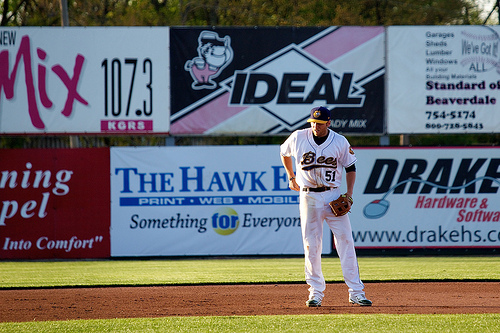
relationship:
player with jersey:
[278, 106, 375, 309] [276, 124, 361, 189]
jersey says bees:
[276, 124, 361, 189] [300, 150, 339, 165]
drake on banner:
[370, 157, 500, 194] [340, 156, 498, 248]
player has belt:
[278, 106, 375, 309] [303, 186, 336, 193]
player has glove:
[278, 106, 375, 309] [330, 193, 358, 218]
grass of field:
[4, 256, 500, 287] [5, 259, 499, 333]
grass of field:
[18, 315, 486, 332] [5, 259, 499, 333]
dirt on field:
[5, 285, 499, 312] [5, 259, 499, 333]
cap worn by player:
[303, 108, 336, 123] [278, 106, 375, 309]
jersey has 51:
[276, 124, 361, 189] [327, 167, 335, 184]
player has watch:
[278, 106, 375, 309] [289, 177, 295, 182]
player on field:
[278, 106, 375, 309] [5, 259, 499, 333]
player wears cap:
[278, 106, 375, 309] [303, 108, 336, 123]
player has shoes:
[278, 106, 375, 309] [347, 289, 377, 308]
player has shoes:
[278, 106, 375, 309] [304, 292, 320, 310]